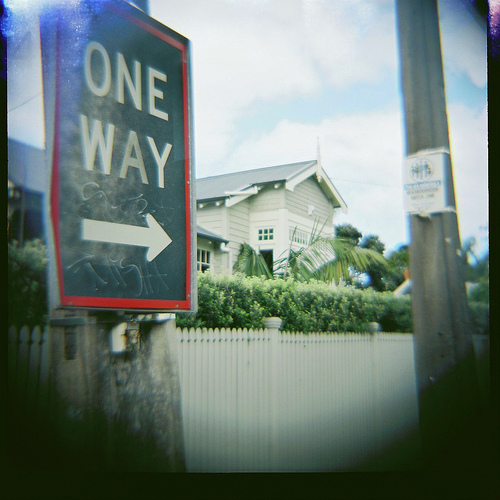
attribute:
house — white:
[6, 137, 349, 276]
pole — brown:
[393, 2, 478, 470]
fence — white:
[1, 325, 498, 474]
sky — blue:
[1, 1, 498, 263]